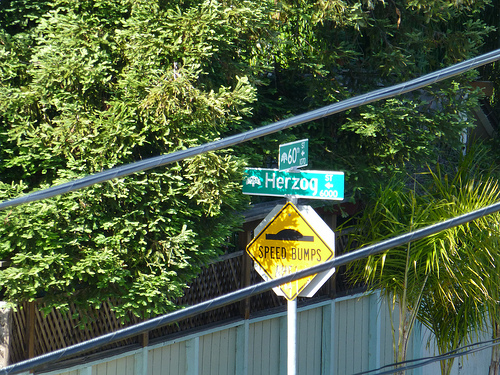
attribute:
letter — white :
[273, 172, 284, 189]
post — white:
[283, 297, 299, 373]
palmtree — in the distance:
[373, 160, 498, 370]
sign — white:
[232, 167, 345, 201]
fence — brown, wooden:
[71, 280, 178, 340]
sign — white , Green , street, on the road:
[238, 168, 346, 202]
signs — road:
[231, 130, 369, 299]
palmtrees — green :
[360, 165, 495, 371]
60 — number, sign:
[285, 147, 297, 164]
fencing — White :
[45, 260, 499, 373]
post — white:
[239, 204, 349, 313]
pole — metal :
[22, 171, 127, 194]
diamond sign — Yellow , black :
[245, 207, 330, 297]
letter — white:
[263, 170, 276, 190]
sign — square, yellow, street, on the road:
[243, 202, 332, 299]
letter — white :
[262, 168, 274, 193]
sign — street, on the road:
[275, 137, 307, 170]